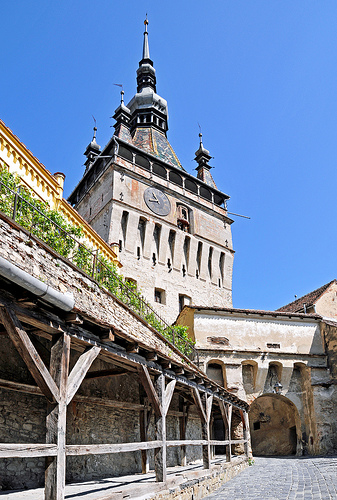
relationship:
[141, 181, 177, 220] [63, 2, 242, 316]
clock on old tower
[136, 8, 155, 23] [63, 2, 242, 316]
flag on top tower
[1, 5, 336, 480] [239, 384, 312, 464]
building has entryway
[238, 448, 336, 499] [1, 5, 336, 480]
pathway leading building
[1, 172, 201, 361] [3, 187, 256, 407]
tiles on roof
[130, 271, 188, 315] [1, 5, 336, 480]
windows on side of building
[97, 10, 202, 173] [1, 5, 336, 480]
steeple on top building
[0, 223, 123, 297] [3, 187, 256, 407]
shingles are on roof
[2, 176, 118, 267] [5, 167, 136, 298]
plants growing on balcony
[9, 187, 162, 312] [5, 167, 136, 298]
railing on balcony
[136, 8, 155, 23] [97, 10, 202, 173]
flag on steeple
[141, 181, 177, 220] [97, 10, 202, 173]
clock face on tower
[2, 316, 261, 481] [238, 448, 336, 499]
wood along pathway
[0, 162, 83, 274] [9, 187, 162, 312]
plants growing along railing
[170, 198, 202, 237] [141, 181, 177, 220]
window next to clock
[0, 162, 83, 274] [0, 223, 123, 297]
plants has shingles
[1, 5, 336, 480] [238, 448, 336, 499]
building has pathway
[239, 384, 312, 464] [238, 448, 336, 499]
tunnel by sidewalk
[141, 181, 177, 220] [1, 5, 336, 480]
clock on building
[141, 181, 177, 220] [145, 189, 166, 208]
clock has hands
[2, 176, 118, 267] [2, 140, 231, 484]
bushes of building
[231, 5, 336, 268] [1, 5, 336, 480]
sky above building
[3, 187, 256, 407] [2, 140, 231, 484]
roof of building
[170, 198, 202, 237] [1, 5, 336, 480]
window on building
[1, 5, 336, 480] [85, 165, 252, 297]
building color light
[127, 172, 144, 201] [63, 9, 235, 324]
stain on old tower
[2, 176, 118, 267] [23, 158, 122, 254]
plants on ledge